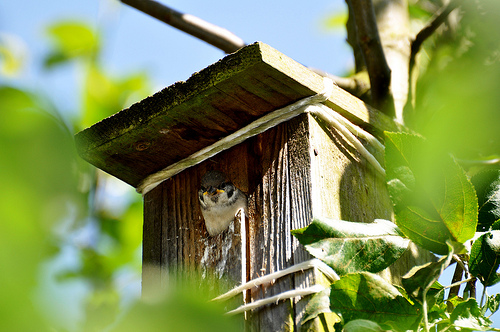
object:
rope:
[207, 252, 327, 317]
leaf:
[467, 230, 500, 284]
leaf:
[326, 274, 414, 330]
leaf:
[381, 130, 478, 254]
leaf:
[290, 217, 413, 269]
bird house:
[72, 41, 425, 330]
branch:
[121, 0, 263, 57]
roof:
[67, 40, 469, 189]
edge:
[380, 124, 406, 234]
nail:
[312, 146, 319, 158]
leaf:
[40, 19, 102, 70]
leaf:
[328, 270, 421, 329]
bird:
[197, 168, 250, 237]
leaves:
[288, 96, 497, 311]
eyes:
[199, 181, 214, 191]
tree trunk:
[345, 5, 412, 119]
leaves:
[362, 122, 479, 329]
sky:
[2, 2, 359, 51]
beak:
[209, 186, 215, 199]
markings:
[198, 181, 239, 201]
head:
[195, 171, 235, 209]